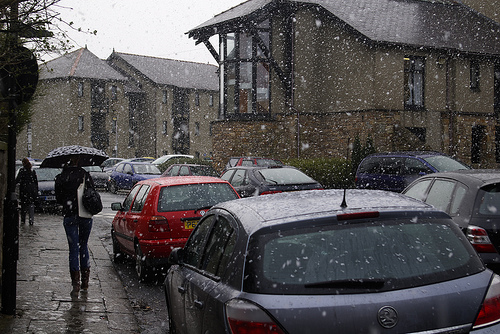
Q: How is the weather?
A: Raining.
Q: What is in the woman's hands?
A: An umbrella.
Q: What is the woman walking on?
A: A sidewalk.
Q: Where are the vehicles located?
A: On the driveway.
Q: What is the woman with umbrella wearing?
A: Pants.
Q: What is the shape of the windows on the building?
A: Rectangular.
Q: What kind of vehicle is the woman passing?
A: A red one.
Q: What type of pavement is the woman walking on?
A: Brick.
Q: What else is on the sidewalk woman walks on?
A: Another person.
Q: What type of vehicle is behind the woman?
A: A four door vehicle.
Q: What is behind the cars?
A: Buildings.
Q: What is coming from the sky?
A: Snow.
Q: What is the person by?
A: Red car.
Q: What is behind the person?
A: Blue car.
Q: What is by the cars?
A: Tan building.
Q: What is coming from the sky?
A: Snow.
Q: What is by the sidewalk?
A: Red car by curb.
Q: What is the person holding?
A: Umbrella.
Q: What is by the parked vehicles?
A: Car driving.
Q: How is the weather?
A: Snowing.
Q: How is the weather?
A: Cold.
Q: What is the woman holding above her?
A: An umbrella.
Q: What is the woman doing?
A: Walking.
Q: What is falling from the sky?
A: Snow.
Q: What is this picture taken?
A: The city.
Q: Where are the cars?
A: The street.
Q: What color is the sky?
A: White.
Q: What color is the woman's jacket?
A: Black.